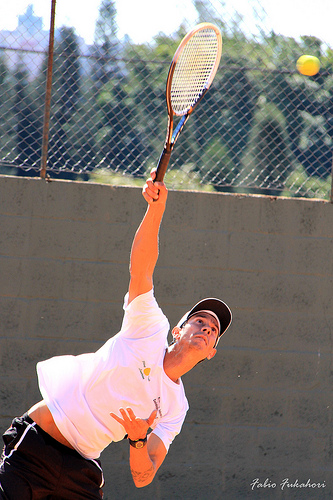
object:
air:
[235, 87, 328, 236]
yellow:
[302, 61, 312, 70]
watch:
[126, 435, 148, 451]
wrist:
[128, 436, 147, 449]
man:
[0, 167, 230, 500]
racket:
[152, 21, 222, 203]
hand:
[141, 167, 168, 208]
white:
[103, 371, 123, 396]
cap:
[177, 297, 233, 349]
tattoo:
[128, 462, 155, 482]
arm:
[126, 205, 165, 324]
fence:
[0, 0, 333, 198]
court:
[0, 0, 333, 500]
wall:
[0, 178, 333, 500]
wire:
[65, 63, 126, 141]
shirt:
[34, 288, 189, 460]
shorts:
[0, 410, 106, 500]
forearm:
[131, 204, 164, 254]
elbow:
[130, 472, 152, 488]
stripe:
[0, 419, 36, 471]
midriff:
[27, 398, 73, 447]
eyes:
[195, 317, 204, 325]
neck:
[165, 344, 190, 380]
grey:
[192, 222, 252, 287]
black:
[26, 453, 49, 491]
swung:
[121, 23, 223, 325]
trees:
[249, 103, 293, 197]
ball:
[296, 55, 323, 77]